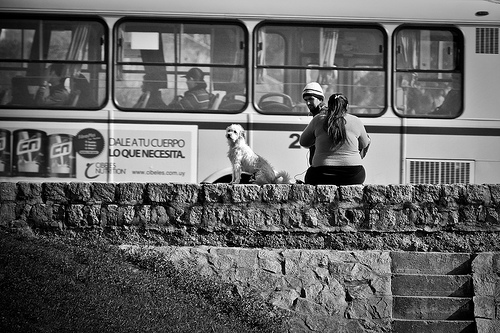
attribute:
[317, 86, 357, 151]
dark hair — long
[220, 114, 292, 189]
dog — white, large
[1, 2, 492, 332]
scene — daytime, black, white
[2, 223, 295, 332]
slope — grassy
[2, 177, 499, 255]
wall — rocky, bricked, stoned, rock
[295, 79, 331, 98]
knit cap — beanie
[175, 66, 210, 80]
cap — dark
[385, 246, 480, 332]
steps — concrete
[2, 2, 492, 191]
bus — big, closed